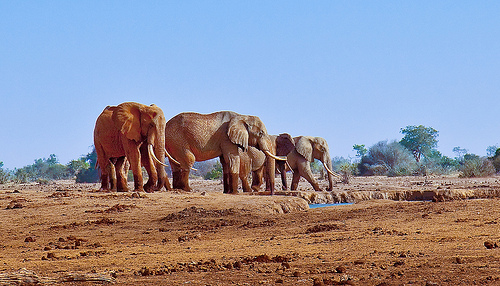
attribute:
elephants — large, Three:
[64, 64, 401, 215]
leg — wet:
[125, 149, 149, 195]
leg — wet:
[140, 151, 155, 193]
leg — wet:
[95, 164, 112, 191]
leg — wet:
[110, 160, 127, 191]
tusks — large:
[147, 142, 182, 165]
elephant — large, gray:
[93, 102, 179, 192]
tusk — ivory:
[145, 142, 167, 167]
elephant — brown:
[89, 99, 171, 196]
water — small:
[308, 198, 357, 208]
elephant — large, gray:
[162, 110, 289, 191]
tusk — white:
[254, 151, 286, 176]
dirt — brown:
[3, 159, 495, 284]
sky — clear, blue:
[0, 0, 498, 170]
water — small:
[314, 196, 352, 211]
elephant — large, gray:
[271, 129, 339, 192]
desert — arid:
[0, 152, 498, 284]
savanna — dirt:
[0, 125, 494, 283]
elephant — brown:
[163, 110, 283, 200]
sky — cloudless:
[32, 7, 202, 79]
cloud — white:
[429, 71, 484, 137]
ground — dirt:
[2, 171, 484, 283]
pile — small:
[163, 203, 260, 236]